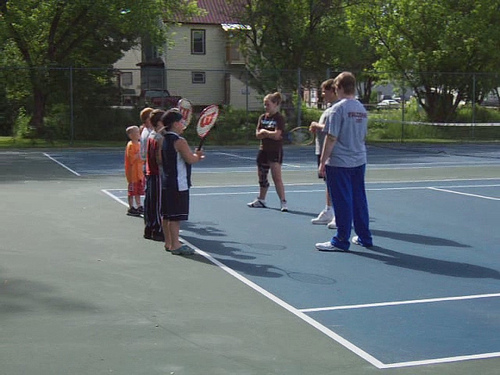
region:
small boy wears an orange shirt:
[110, 115, 147, 220]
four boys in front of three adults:
[106, 85, 236, 274]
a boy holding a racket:
[153, 99, 233, 264]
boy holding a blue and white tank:
[151, 103, 228, 265]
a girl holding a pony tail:
[246, 85, 301, 222]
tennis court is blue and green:
[36, 131, 498, 373]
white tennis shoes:
[310, 231, 376, 256]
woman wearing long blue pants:
[309, 65, 384, 264]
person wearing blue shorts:
[302, 77, 339, 232]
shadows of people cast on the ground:
[194, 214, 332, 304]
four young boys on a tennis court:
[108, 87, 221, 260]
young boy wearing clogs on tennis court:
[149, 235, 206, 266]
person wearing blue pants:
[313, 54, 379, 256]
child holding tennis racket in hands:
[153, 105, 218, 176]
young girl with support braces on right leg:
[241, 88, 298, 218]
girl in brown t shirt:
[246, 73, 288, 155]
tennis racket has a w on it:
[198, 99, 217, 153]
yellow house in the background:
[72, 5, 295, 112]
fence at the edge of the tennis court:
[29, 45, 86, 150]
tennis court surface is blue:
[220, 238, 406, 306]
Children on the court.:
[51, 71, 431, 271]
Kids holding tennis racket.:
[187, 106, 229, 149]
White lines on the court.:
[222, 243, 457, 372]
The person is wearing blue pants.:
[310, 156, 397, 266]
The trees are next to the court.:
[247, 13, 477, 86]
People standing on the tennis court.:
[295, 64, 385, 246]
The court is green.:
[29, 223, 156, 360]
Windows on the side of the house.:
[171, 19, 234, 100]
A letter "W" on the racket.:
[194, 102, 224, 142]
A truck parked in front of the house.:
[126, 73, 190, 113]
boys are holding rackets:
[173, 85, 232, 151]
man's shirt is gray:
[319, 92, 383, 181]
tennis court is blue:
[135, 167, 492, 370]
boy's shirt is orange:
[120, 133, 148, 187]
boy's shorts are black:
[162, 179, 187, 218]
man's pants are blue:
[318, 157, 370, 254]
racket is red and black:
[186, 99, 229, 151]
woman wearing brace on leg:
[248, 150, 272, 198]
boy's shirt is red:
[145, 134, 160, 175]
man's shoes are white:
[310, 227, 392, 269]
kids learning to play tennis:
[94, 72, 244, 242]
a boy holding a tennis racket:
[157, 93, 218, 260]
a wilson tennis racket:
[182, 83, 222, 165]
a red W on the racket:
[196, 107, 218, 134]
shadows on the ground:
[360, 209, 485, 306]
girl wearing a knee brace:
[236, 137, 278, 210]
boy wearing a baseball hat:
[148, 106, 191, 141]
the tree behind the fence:
[0, 8, 116, 135]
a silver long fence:
[27, 57, 473, 131]